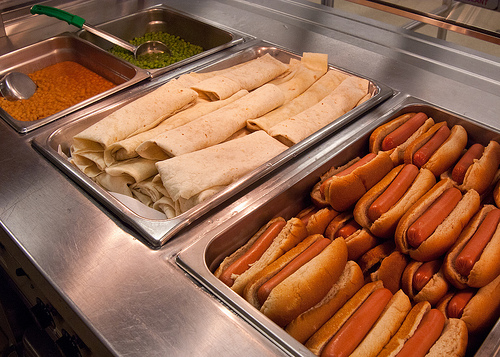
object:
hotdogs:
[447, 142, 486, 186]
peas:
[152, 34, 159, 39]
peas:
[185, 48, 193, 53]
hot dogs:
[408, 258, 441, 294]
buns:
[242, 233, 347, 320]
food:
[70, 76, 198, 158]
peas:
[142, 36, 150, 41]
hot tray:
[78, 7, 236, 78]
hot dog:
[221, 219, 283, 283]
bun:
[214, 215, 303, 292]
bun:
[302, 280, 411, 357]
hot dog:
[256, 236, 329, 300]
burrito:
[155, 128, 289, 201]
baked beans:
[68, 77, 77, 85]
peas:
[119, 55, 127, 59]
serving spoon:
[28, 3, 172, 61]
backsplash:
[348, 0, 498, 43]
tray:
[1, 30, 151, 135]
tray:
[178, 95, 498, 355]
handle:
[27, 3, 86, 27]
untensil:
[30, 1, 170, 59]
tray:
[76, 1, 244, 81]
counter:
[0, 0, 497, 354]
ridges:
[220, 0, 499, 100]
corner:
[135, 214, 180, 247]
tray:
[31, 40, 395, 248]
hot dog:
[396, 306, 444, 355]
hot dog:
[322, 286, 392, 355]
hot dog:
[405, 184, 462, 246]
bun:
[375, 300, 470, 355]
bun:
[391, 178, 481, 261]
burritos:
[102, 89, 250, 169]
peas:
[162, 39, 168, 41]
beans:
[109, 48, 117, 52]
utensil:
[1, 59, 119, 119]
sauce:
[0, 59, 118, 119]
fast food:
[0, 30, 499, 354]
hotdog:
[367, 162, 417, 217]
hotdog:
[380, 109, 428, 149]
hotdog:
[414, 124, 451, 163]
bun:
[354, 161, 435, 233]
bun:
[370, 110, 432, 161]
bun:
[404, 118, 467, 173]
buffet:
[1, 0, 499, 353]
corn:
[90, 75, 97, 78]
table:
[1, 1, 461, 352]